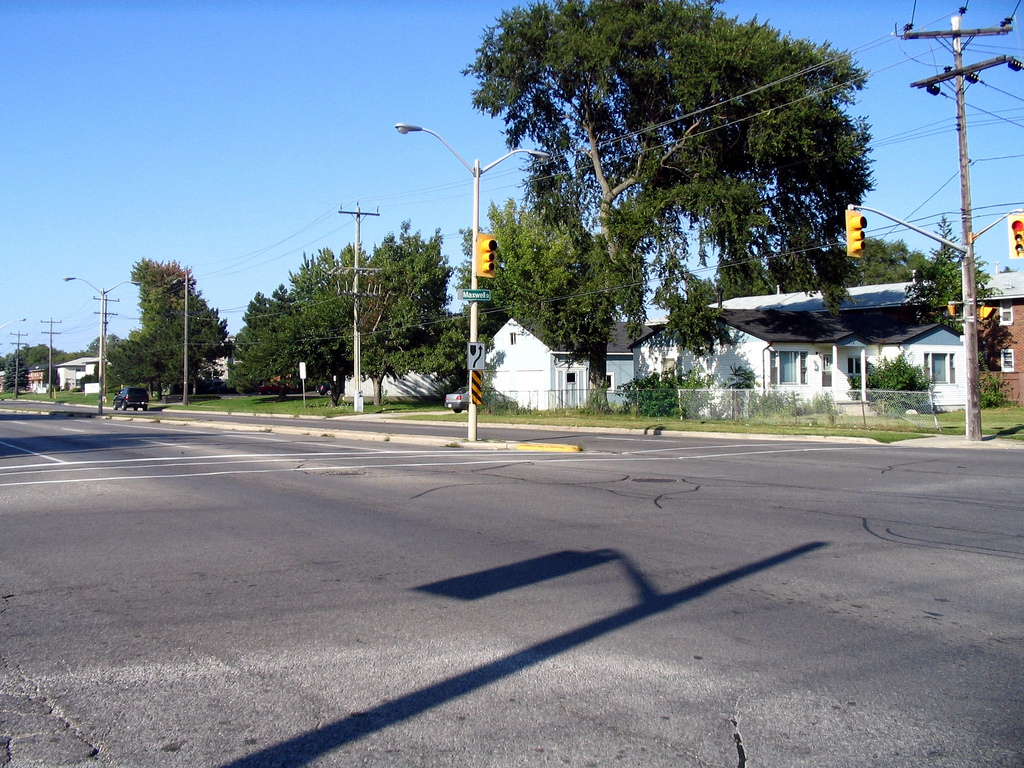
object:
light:
[395, 126, 408, 134]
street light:
[395, 122, 551, 442]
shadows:
[208, 541, 830, 765]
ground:
[0, 414, 1022, 767]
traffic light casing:
[476, 233, 496, 278]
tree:
[455, 0, 872, 414]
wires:
[0, 0, 1022, 350]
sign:
[468, 341, 485, 369]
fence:
[482, 389, 944, 432]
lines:
[0, 442, 876, 487]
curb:
[0, 398, 1022, 454]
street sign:
[458, 289, 491, 301]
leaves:
[518, 43, 802, 229]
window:
[1000, 349, 1013, 373]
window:
[848, 357, 861, 374]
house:
[632, 308, 968, 419]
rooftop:
[625, 305, 990, 350]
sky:
[0, 0, 1022, 349]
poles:
[63, 276, 143, 415]